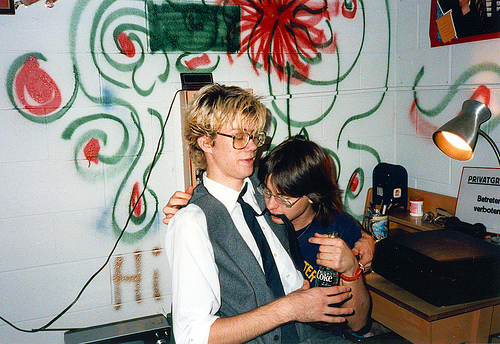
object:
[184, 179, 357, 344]
grey vest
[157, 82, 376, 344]
man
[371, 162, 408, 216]
container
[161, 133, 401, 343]
man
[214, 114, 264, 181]
face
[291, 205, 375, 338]
shirt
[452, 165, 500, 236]
sign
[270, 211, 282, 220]
mouth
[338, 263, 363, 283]
watch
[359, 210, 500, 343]
desk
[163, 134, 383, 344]
lady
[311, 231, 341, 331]
bottle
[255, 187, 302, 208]
eyeglasses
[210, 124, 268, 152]
eyeglasses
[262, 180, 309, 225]
woman's face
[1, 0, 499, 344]
wall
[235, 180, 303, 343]
blue tie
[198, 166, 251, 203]
neck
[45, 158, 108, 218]
brick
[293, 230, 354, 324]
hands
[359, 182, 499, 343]
table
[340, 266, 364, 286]
wrist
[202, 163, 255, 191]
neck